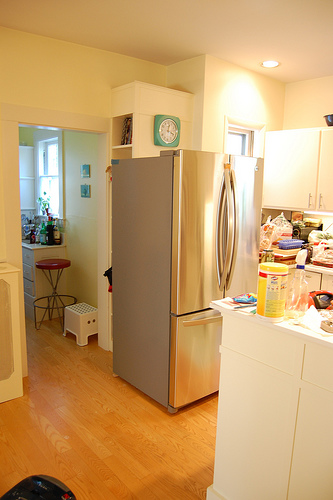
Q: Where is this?
A: This is at the kitchen.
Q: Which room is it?
A: It is a kitchen.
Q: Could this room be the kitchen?
A: Yes, it is the kitchen.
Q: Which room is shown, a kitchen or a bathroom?
A: It is a kitchen.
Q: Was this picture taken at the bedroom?
A: No, the picture was taken in the kitchen.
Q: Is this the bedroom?
A: No, it is the kitchen.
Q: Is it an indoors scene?
A: Yes, it is indoors.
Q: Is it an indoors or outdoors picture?
A: It is indoors.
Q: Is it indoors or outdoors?
A: It is indoors.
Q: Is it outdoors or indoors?
A: It is indoors.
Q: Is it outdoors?
A: No, it is indoors.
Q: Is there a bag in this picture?
A: Yes, there is a bag.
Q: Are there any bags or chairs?
A: Yes, there is a bag.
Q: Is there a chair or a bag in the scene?
A: Yes, there is a bag.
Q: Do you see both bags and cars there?
A: No, there is a bag but no cars.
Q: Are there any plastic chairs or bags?
A: Yes, there is a plastic bag.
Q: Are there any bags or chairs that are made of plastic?
A: Yes, the bag is made of plastic.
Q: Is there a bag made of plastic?
A: Yes, there is a bag that is made of plastic.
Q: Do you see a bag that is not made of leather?
A: Yes, there is a bag that is made of plastic.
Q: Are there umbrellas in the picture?
A: No, there are no umbrellas.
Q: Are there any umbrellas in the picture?
A: No, there are no umbrellas.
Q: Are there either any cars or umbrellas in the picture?
A: No, there are no umbrellas or cars.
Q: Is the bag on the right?
A: Yes, the bag is on the right of the image.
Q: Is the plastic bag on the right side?
A: Yes, the bag is on the right of the image.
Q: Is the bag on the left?
A: No, the bag is on the right of the image.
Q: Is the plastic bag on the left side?
A: No, the bag is on the right of the image.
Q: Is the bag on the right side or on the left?
A: The bag is on the right of the image.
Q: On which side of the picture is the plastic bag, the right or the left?
A: The bag is on the right of the image.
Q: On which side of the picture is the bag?
A: The bag is on the right of the image.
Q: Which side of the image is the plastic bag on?
A: The bag is on the right of the image.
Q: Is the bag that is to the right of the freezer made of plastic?
A: Yes, the bag is made of plastic.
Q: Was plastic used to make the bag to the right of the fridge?
A: Yes, the bag is made of plastic.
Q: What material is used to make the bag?
A: The bag is made of plastic.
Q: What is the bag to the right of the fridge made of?
A: The bag is made of plastic.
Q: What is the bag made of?
A: The bag is made of plastic.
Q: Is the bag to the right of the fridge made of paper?
A: No, the bag is made of plastic.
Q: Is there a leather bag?
A: No, there is a bag but it is made of plastic.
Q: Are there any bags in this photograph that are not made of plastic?
A: No, there is a bag but it is made of plastic.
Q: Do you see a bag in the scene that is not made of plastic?
A: No, there is a bag but it is made of plastic.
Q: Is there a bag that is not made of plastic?
A: No, there is a bag but it is made of plastic.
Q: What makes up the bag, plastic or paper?
A: The bag is made of plastic.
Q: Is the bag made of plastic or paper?
A: The bag is made of plastic.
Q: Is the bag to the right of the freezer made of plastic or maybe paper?
A: The bag is made of plastic.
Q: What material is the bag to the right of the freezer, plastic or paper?
A: The bag is made of plastic.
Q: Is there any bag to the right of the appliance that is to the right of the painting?
A: Yes, there is a bag to the right of the freezer.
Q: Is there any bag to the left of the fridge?
A: No, the bag is to the right of the fridge.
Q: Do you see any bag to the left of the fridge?
A: No, the bag is to the right of the fridge.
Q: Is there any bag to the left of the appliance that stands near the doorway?
A: No, the bag is to the right of the fridge.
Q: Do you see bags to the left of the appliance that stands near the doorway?
A: No, the bag is to the right of the fridge.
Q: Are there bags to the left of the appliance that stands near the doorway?
A: No, the bag is to the right of the fridge.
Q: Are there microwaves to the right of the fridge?
A: No, there is a bag to the right of the fridge.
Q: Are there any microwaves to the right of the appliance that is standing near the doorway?
A: No, there is a bag to the right of the fridge.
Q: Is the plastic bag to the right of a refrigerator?
A: Yes, the bag is to the right of a refrigerator.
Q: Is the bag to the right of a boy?
A: No, the bag is to the right of a refrigerator.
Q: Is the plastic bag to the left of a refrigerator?
A: No, the bag is to the right of a refrigerator.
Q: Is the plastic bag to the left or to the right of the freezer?
A: The bag is to the right of the freezer.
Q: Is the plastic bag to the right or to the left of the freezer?
A: The bag is to the right of the freezer.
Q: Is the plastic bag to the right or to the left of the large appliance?
A: The bag is to the right of the freezer.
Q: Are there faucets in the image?
A: No, there are no faucets.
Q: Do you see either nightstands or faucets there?
A: No, there are no faucets or nightstands.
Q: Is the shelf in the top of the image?
A: Yes, the shelf is in the top of the image.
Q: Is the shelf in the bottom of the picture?
A: No, the shelf is in the top of the image.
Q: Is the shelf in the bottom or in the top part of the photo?
A: The shelf is in the top of the image.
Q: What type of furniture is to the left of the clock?
A: The piece of furniture is a shelf.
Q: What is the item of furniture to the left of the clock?
A: The piece of furniture is a shelf.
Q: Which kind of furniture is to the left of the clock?
A: The piece of furniture is a shelf.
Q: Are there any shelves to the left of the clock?
A: Yes, there is a shelf to the left of the clock.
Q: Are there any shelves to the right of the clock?
A: No, the shelf is to the left of the clock.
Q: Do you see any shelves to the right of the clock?
A: No, the shelf is to the left of the clock.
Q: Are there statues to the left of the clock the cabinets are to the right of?
A: No, there is a shelf to the left of the clock.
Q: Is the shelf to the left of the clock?
A: Yes, the shelf is to the left of the clock.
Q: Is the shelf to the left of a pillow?
A: No, the shelf is to the left of the clock.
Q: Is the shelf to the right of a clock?
A: No, the shelf is to the left of a clock.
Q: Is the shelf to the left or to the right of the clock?
A: The shelf is to the left of the clock.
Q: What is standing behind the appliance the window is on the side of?
A: The shelf is standing behind the refrigerator.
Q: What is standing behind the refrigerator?
A: The shelf is standing behind the refrigerator.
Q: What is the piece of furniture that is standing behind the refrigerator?
A: The piece of furniture is a shelf.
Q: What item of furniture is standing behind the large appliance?
A: The piece of furniture is a shelf.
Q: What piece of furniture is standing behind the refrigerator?
A: The piece of furniture is a shelf.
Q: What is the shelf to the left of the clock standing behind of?
A: The shelf is standing behind the refrigerator.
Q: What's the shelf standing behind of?
A: The shelf is standing behind the refrigerator.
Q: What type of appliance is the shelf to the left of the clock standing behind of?
A: The shelf is standing behind the refrigerator.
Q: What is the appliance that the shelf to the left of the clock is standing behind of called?
A: The appliance is a refrigerator.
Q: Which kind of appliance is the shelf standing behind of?
A: The shelf is standing behind the refrigerator.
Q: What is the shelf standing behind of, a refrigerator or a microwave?
A: The shelf is standing behind a refrigerator.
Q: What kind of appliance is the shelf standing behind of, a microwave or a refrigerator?
A: The shelf is standing behind a refrigerator.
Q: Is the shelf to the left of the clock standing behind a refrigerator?
A: Yes, the shelf is standing behind a refrigerator.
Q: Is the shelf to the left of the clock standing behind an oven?
A: No, the shelf is standing behind a refrigerator.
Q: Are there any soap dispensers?
A: No, there are no soap dispensers.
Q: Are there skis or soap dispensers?
A: No, there are no soap dispensers or skis.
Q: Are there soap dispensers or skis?
A: No, there are no soap dispensers or skis.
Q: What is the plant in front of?
A: The plant is in front of the window.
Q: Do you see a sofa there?
A: No, there are no sofas.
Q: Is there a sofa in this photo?
A: No, there are no sofas.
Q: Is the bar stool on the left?
A: Yes, the bar stool is on the left of the image.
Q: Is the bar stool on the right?
A: No, the bar stool is on the left of the image.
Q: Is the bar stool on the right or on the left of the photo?
A: The bar stool is on the left of the image.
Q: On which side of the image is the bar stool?
A: The bar stool is on the left of the image.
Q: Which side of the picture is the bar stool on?
A: The bar stool is on the left of the image.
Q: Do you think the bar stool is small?
A: Yes, the bar stool is small.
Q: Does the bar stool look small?
A: Yes, the bar stool is small.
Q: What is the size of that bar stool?
A: The bar stool is small.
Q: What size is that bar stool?
A: The bar stool is small.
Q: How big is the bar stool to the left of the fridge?
A: The bar stool is small.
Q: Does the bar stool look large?
A: No, the bar stool is small.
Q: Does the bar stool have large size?
A: No, the bar stool is small.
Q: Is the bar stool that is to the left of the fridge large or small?
A: The bar stool is small.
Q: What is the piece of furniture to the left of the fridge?
A: The piece of furniture is a bar stool.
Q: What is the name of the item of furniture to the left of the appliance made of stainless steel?
A: The piece of furniture is a bar stool.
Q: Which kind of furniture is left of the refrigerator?
A: The piece of furniture is a bar stool.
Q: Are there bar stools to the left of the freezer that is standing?
A: Yes, there is a bar stool to the left of the freezer.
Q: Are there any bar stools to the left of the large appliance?
A: Yes, there is a bar stool to the left of the freezer.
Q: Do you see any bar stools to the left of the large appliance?
A: Yes, there is a bar stool to the left of the freezer.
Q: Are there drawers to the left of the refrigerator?
A: No, there is a bar stool to the left of the refrigerator.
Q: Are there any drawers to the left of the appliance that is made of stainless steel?
A: No, there is a bar stool to the left of the refrigerator.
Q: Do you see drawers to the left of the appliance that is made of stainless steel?
A: No, there is a bar stool to the left of the refrigerator.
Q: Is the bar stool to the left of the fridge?
A: Yes, the bar stool is to the left of the fridge.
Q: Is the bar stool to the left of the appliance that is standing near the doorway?
A: Yes, the bar stool is to the left of the fridge.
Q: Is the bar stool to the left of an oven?
A: No, the bar stool is to the left of the fridge.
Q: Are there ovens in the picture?
A: No, there are no ovens.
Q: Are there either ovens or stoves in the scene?
A: No, there are no ovens or stoves.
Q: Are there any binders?
A: No, there are no binders.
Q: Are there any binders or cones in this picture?
A: No, there are no binders or cones.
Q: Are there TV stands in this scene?
A: No, there are no TV stands.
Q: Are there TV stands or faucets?
A: No, there are no TV stands or faucets.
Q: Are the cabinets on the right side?
A: Yes, the cabinets are on the right of the image.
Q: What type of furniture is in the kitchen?
A: The pieces of furniture are cabinets.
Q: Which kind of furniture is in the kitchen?
A: The pieces of furniture are cabinets.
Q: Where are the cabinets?
A: The cabinets are in the kitchen.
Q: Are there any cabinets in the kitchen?
A: Yes, there are cabinets in the kitchen.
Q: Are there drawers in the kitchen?
A: No, there are cabinets in the kitchen.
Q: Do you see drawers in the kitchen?
A: No, there are cabinets in the kitchen.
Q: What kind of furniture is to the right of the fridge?
A: The pieces of furniture are cabinets.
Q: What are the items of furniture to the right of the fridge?
A: The pieces of furniture are cabinets.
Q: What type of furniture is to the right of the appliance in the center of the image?
A: The pieces of furniture are cabinets.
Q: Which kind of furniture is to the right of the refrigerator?
A: The pieces of furniture are cabinets.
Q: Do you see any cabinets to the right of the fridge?
A: Yes, there are cabinets to the right of the fridge.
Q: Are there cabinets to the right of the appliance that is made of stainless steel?
A: Yes, there are cabinets to the right of the fridge.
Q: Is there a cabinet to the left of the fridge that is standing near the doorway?
A: No, the cabinets are to the right of the fridge.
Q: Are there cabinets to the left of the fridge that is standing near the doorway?
A: No, the cabinets are to the right of the fridge.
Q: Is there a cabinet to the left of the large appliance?
A: No, the cabinets are to the right of the fridge.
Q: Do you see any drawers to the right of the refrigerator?
A: No, there are cabinets to the right of the refrigerator.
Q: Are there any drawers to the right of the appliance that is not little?
A: No, there are cabinets to the right of the refrigerator.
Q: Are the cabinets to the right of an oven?
A: No, the cabinets are to the right of the freezer.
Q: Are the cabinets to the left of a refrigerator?
A: No, the cabinets are to the right of a refrigerator.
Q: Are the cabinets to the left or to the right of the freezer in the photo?
A: The cabinets are to the right of the freezer.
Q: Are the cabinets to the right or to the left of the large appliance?
A: The cabinets are to the right of the freezer.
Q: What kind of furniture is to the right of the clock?
A: The pieces of furniture are cabinets.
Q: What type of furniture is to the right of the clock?
A: The pieces of furniture are cabinets.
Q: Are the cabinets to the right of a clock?
A: Yes, the cabinets are to the right of a clock.